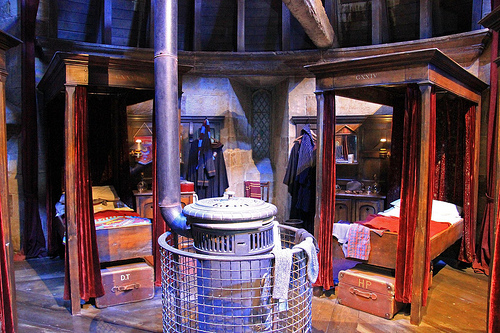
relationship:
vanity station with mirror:
[325, 121, 381, 242] [331, 126, 353, 163]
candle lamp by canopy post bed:
[134, 137, 144, 155] [58, 46, 179, 301]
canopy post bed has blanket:
[58, 46, 179, 301] [82, 203, 136, 222]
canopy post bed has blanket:
[315, 58, 485, 321] [361, 212, 455, 244]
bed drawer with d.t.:
[87, 260, 153, 305] [119, 271, 135, 282]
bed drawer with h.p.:
[331, 260, 397, 320] [357, 276, 376, 292]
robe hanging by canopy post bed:
[192, 134, 223, 199] [58, 46, 179, 301]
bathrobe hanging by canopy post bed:
[294, 126, 321, 206] [315, 58, 485, 321]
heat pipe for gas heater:
[148, 4, 187, 234] [184, 189, 281, 330]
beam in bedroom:
[282, 1, 337, 46] [3, 2, 499, 325]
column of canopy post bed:
[66, 64, 99, 310] [58, 46, 179, 301]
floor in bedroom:
[17, 243, 499, 332] [3, 2, 499, 325]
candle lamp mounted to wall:
[134, 137, 144, 155] [40, 49, 398, 276]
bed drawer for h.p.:
[87, 260, 153, 305] [357, 276, 376, 292]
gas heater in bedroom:
[184, 189, 281, 330] [3, 2, 499, 325]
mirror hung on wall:
[331, 126, 353, 163] [40, 49, 398, 276]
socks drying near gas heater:
[270, 234, 324, 312] [184, 189, 281, 330]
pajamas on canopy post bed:
[341, 218, 380, 264] [315, 58, 485, 321]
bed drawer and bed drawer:
[87, 260, 153, 305] [331, 260, 397, 320]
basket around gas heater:
[156, 231, 319, 332] [184, 189, 281, 330]